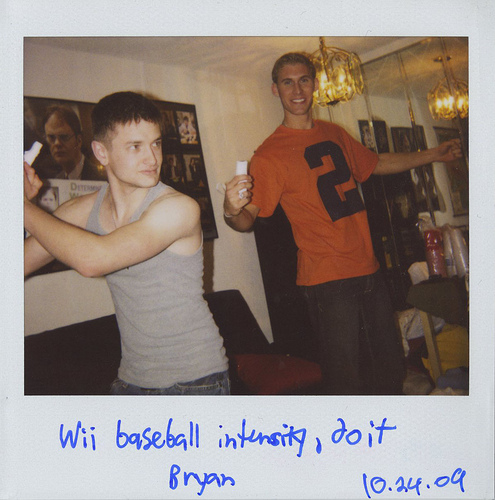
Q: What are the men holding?
A: Game controllers.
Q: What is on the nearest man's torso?
A: A gray tank top.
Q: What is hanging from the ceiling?
A: Lights.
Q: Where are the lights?
A: Hanging from the ceiling.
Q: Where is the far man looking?
A: At the camera.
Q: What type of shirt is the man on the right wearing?
A: Tank top.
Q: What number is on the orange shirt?
A: 2.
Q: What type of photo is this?
A: Polaroid.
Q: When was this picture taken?
A: 10/24/09.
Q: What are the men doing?
A: Playing Wii.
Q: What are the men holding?
A: Wii remote.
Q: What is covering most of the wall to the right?
A: Mirror.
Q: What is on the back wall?
A: Pictures.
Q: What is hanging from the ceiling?
A: Lights.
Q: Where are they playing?
A: In the living room.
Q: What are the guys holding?
A: Controllers.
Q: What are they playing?
A: Wii.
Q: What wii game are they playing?
A: Baseball.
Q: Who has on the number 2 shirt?
A: The taller guy.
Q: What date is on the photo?
A: 10-24-09.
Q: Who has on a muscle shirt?
A: The shorter guy.